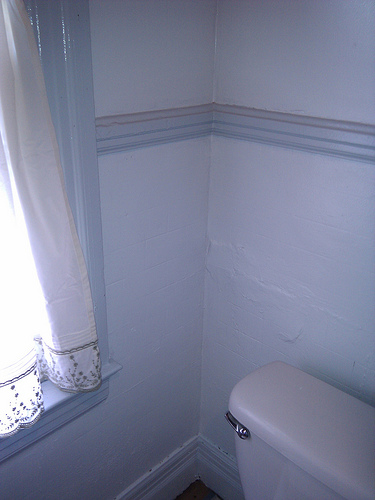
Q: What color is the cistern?
A: White.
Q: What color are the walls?
A: White.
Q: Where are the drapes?
A: Over the window.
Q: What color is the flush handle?
A: Silver.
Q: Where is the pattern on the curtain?
A: On the bottom.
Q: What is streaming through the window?
A: Sunlight.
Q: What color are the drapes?
A: White.